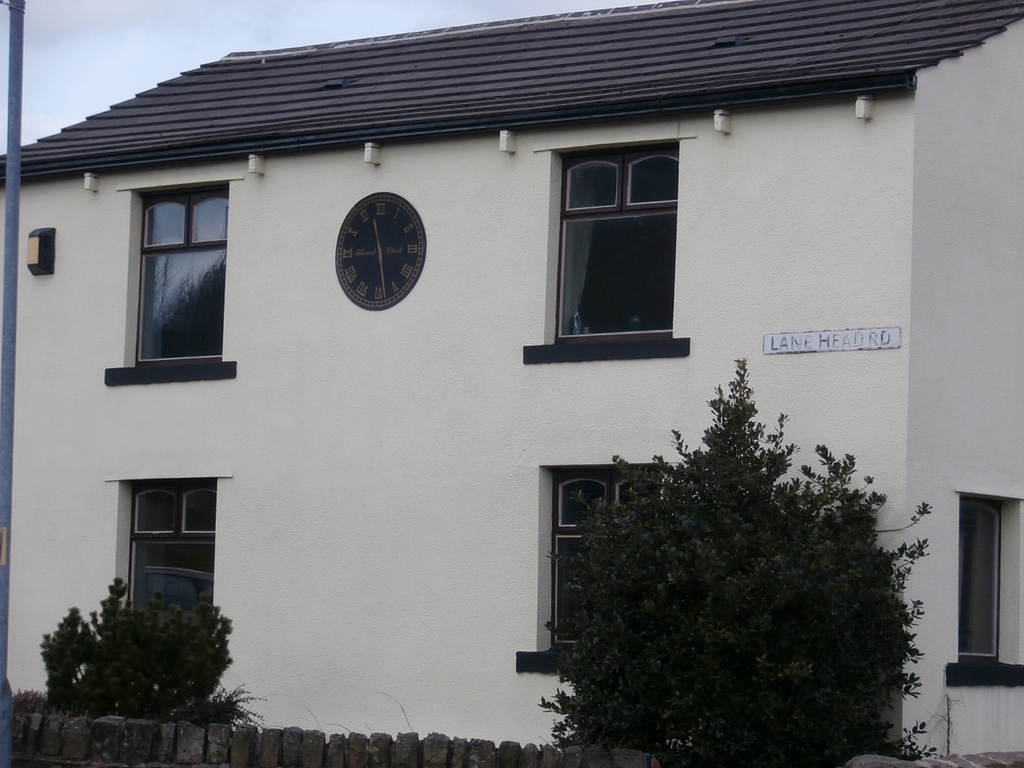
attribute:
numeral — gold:
[367, 188, 393, 217]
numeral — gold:
[394, 218, 417, 235]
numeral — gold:
[400, 237, 420, 254]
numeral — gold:
[405, 256, 419, 283]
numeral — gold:
[369, 285, 393, 304]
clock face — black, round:
[335, 188, 428, 310]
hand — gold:
[372, 213, 388, 248]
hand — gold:
[373, 242, 394, 306]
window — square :
[556, 219, 671, 333]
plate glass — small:
[141, 199, 187, 244]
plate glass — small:
[187, 199, 230, 244]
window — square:
[133, 251, 222, 360]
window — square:
[132, 541, 213, 612]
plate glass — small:
[136, 481, 176, 535]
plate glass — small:
[177, 481, 215, 535]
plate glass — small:
[556, 475, 599, 527]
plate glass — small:
[612, 475, 651, 527]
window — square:
[544, 529, 586, 651]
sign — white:
[759, 321, 909, 354]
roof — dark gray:
[3, 4, 1022, 185]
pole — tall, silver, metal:
[5, 1, 28, 766]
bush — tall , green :
[553, 360, 931, 753]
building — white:
[2, 10, 1023, 753]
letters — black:
[755, 336, 922, 360]